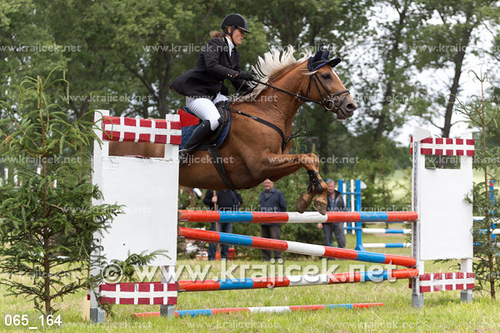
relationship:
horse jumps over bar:
[108, 50, 356, 203] [177, 225, 417, 266]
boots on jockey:
[181, 117, 221, 166] [171, 12, 253, 162]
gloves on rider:
[235, 66, 258, 89] [169, 12, 248, 159]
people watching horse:
[199, 178, 349, 262] [108, 50, 356, 203]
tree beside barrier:
[0, 65, 169, 320] [87, 107, 477, 315]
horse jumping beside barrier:
[108, 50, 356, 203] [87, 107, 477, 315]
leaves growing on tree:
[1, 64, 172, 299] [0, 65, 169, 320]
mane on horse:
[202, 62, 309, 111] [135, 50, 354, 208]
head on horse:
[278, 19, 375, 129] [135, 50, 354, 208]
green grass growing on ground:
[346, 276, 429, 320] [0, 240, 500, 330]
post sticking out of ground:
[348, 176, 365, 264] [16, 289, 498, 331]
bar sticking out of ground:
[178, 209, 416, 223] [16, 289, 498, 331]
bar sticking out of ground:
[177, 225, 417, 266] [16, 289, 498, 331]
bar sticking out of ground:
[179, 266, 415, 292] [16, 289, 498, 331]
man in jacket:
[246, 162, 289, 251] [252, 186, 290, 227]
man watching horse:
[246, 162, 289, 251] [128, 55, 435, 245]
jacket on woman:
[178, 31, 246, 96] [173, 26, 250, 151]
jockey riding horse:
[171, 12, 253, 162] [108, 50, 356, 203]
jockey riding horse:
[171, 12, 253, 162] [104, 48, 351, 229]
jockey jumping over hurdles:
[171, 12, 253, 162] [95, 80, 488, 298]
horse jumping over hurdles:
[108, 50, 356, 203] [91, 44, 398, 214]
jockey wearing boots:
[171, 12, 253, 162] [178, 119, 220, 159]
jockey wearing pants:
[171, 12, 253, 162] [181, 92, 232, 161]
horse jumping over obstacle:
[108, 50, 356, 203] [184, 201, 414, 311]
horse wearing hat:
[115, 20, 360, 213] [211, 10, 254, 42]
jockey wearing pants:
[171, 12, 253, 162] [184, 90, 229, 130]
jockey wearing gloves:
[171, 12, 253, 162] [227, 55, 262, 86]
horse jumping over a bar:
[108, 50, 356, 203] [177, 225, 417, 266]